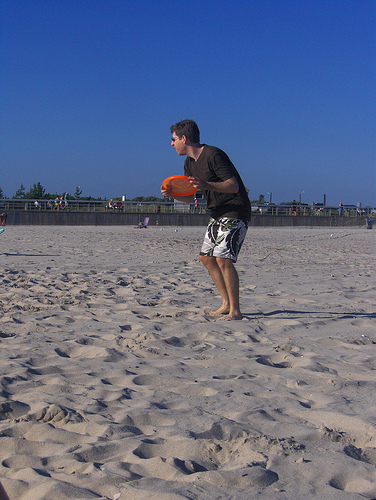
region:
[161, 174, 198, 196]
an orange Frisbee at the beach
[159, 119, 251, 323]
a man playing with a Frisbee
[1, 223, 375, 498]
soft sand at the beach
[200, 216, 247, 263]
the man is wearing a white and green floral shorts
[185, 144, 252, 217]
the man is wearing a brown shirt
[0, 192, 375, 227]
a boardwalk runs along the beach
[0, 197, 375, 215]
a fence railing runs along the boardwalk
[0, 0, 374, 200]
clear blue sky without any clouds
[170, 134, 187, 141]
the man is wearing dark sunglasses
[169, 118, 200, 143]
the man has dark brown hair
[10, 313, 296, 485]
Footprints in the sand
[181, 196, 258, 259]
Blue, green, and white swim shorts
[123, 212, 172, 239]
A chair sitting on the beach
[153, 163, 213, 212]
A bright orange frisbee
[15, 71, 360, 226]
A bright blue sky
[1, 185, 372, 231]
A long pier along the beach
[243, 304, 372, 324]
The man's shadow in the sand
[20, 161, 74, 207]
Trees in the background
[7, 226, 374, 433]
A large sandy beach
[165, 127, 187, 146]
Sunglasses on the man's face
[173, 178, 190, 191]
orange frisbee in man's hand.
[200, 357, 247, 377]
sand on the ground.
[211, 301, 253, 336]
man's bare feet in the sand.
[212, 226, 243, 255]
flower pattern on man's shorts.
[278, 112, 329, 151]
clear blue sky above.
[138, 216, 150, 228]
purple beach chair.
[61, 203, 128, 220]
fence along the walking path.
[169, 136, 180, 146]
sunglasses on man's face.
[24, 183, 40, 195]
green leaves on trees.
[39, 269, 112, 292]
footprints in the sand.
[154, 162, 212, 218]
the frisbee is orange.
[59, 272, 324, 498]
the sand is tan.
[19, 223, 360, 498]
feet marks in the sand.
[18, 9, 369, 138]
the sky is blue.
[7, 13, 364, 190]
zero clouds in the sky.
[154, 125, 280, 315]
the man is playing frisbee.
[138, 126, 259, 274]
the man's shirt is black.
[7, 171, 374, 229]
the fence is wood.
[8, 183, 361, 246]
the fence is brown.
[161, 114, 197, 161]
the man has dark hair.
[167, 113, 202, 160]
the head of a man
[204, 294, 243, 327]
the feet of a man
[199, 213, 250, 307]
the legs of a man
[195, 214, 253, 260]
gray and black shorts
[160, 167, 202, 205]
an orange Frisbee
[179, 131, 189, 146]
the ear of the man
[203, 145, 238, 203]
the arm of a man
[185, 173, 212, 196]
the hand of a man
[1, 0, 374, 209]
a clear blue sky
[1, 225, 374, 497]
a tan sandy beach